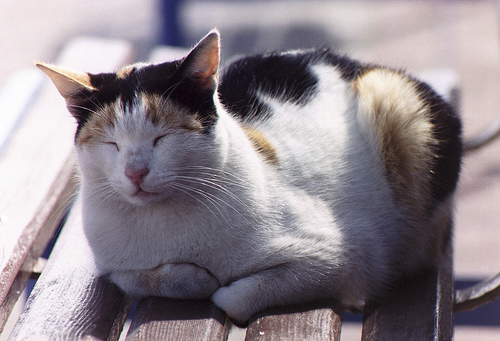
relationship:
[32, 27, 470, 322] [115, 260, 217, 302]
cat has paw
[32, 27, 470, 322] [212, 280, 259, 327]
cat has paw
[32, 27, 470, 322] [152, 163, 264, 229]
cat has cat's whiskers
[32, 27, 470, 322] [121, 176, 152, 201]
cat has mouth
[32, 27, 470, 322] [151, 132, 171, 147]
cat has eye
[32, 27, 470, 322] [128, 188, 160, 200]
cat has mouth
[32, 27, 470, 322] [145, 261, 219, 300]
cat has paw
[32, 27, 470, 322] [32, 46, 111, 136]
cat has ear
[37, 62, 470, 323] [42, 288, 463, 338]
cat on bench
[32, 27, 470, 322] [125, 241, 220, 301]
cat has paw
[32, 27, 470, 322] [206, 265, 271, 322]
cat has paw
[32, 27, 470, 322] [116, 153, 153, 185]
cat has nose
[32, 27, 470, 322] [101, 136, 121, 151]
cat has eye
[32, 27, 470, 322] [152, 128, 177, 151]
cat has eye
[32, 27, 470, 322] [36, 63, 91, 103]
cat has ear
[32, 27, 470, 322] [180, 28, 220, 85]
cat has ear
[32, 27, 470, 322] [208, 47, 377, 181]
cat has back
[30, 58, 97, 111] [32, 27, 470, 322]
ear on cat